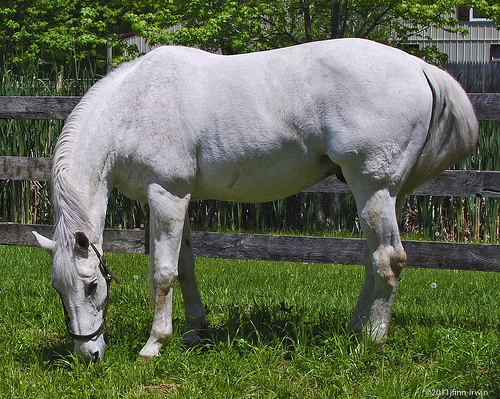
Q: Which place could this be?
A: It is a field.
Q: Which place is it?
A: It is a field.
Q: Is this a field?
A: Yes, it is a field.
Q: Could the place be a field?
A: Yes, it is a field.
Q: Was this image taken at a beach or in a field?
A: It was taken at a field.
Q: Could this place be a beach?
A: No, it is a field.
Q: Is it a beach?
A: No, it is a field.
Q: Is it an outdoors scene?
A: Yes, it is outdoors.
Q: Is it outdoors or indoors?
A: It is outdoors.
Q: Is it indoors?
A: No, it is outdoors.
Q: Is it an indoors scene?
A: No, it is outdoors.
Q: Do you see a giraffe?
A: No, there are no giraffes.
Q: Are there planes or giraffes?
A: No, there are no giraffes or planes.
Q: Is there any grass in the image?
A: Yes, there is grass.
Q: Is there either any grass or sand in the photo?
A: Yes, there is grass.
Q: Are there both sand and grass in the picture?
A: No, there is grass but no sand.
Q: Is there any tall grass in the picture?
A: Yes, there is tall grass.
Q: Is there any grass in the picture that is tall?
A: Yes, there is tall grass.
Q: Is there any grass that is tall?
A: Yes, there is grass that is tall.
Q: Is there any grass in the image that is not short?
A: Yes, there is tall grass.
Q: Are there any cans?
A: No, there are no cans.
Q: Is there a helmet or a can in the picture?
A: No, there are no cans or helmets.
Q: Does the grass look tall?
A: Yes, the grass is tall.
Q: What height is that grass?
A: The grass is tall.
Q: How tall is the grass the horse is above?
A: The grass is tall.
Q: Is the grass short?
A: No, the grass is tall.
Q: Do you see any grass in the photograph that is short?
A: No, there is grass but it is tall.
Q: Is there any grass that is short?
A: No, there is grass but it is tall.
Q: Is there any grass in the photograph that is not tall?
A: No, there is grass but it is tall.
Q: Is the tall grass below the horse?
A: Yes, the grass is below the horse.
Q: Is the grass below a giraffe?
A: No, the grass is below the horse.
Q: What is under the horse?
A: The grass is under the horse.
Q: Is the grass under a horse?
A: Yes, the grass is under a horse.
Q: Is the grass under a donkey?
A: No, the grass is under a horse.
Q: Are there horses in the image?
A: Yes, there is a horse.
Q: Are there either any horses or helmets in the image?
A: Yes, there is a horse.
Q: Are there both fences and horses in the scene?
A: Yes, there are both a horse and a fence.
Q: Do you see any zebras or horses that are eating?
A: Yes, the horse is eating.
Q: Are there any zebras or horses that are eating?
A: Yes, the horse is eating.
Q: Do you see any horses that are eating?
A: Yes, there is a horse that is eating.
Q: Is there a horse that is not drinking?
A: Yes, there is a horse that is eating.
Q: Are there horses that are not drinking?
A: Yes, there is a horse that is eating.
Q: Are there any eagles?
A: No, there are no eagles.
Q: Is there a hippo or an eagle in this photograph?
A: No, there are no eagles or hippos.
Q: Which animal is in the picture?
A: The animal is a horse.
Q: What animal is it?
A: The animal is a horse.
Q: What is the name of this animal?
A: This is a horse.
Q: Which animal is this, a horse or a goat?
A: This is a horse.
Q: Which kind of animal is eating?
A: The animal is a horse.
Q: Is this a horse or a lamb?
A: This is a horse.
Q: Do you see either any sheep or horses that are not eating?
A: No, there is a horse but it is eating.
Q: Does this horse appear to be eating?
A: Yes, the horse is eating.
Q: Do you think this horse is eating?
A: Yes, the horse is eating.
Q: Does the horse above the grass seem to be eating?
A: Yes, the horse is eating.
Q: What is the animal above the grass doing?
A: The horse is eating.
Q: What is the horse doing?
A: The horse is eating.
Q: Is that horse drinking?
A: No, the horse is eating.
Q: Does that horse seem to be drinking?
A: No, the horse is eating.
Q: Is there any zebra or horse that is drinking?
A: No, there is a horse but it is eating.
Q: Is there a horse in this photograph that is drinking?
A: No, there is a horse but it is eating.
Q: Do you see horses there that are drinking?
A: No, there is a horse but it is eating.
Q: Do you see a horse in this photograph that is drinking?
A: No, there is a horse but it is eating.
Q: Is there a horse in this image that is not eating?
A: No, there is a horse but it is eating.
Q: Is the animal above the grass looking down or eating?
A: The horse is eating.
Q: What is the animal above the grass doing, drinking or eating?
A: The horse is eating.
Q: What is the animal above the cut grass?
A: The animal is a horse.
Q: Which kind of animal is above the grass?
A: The animal is a horse.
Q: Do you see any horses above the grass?
A: Yes, there is a horse above the grass.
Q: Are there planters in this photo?
A: No, there are no planters.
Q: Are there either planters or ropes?
A: No, there are no planters or ropes.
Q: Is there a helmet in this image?
A: No, there are no helmets.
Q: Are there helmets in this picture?
A: No, there are no helmets.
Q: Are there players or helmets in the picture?
A: No, there are no helmets or players.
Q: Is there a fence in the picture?
A: Yes, there is a fence.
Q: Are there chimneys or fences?
A: Yes, there is a fence.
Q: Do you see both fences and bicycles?
A: No, there is a fence but no bikes.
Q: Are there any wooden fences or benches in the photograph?
A: Yes, there is a wood fence.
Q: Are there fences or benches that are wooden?
A: Yes, the fence is wooden.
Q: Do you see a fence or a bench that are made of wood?
A: Yes, the fence is made of wood.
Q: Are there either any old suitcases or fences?
A: Yes, there is an old fence.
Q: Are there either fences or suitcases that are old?
A: Yes, the fence is old.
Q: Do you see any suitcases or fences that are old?
A: Yes, the fence is old.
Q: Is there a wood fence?
A: Yes, there is a fence that is made of wood.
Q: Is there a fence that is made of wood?
A: Yes, there is a fence that is made of wood.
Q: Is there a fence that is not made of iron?
A: Yes, there is a fence that is made of wood.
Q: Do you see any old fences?
A: Yes, there is an old fence.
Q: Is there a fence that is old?
A: Yes, there is a fence that is old.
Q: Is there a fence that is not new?
A: Yes, there is a old fence.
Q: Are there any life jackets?
A: No, there are no life jackets.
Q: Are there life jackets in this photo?
A: No, there are no life jackets.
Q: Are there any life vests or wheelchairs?
A: No, there are no life vests or wheelchairs.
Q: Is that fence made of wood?
A: Yes, the fence is made of wood.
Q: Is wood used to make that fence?
A: Yes, the fence is made of wood.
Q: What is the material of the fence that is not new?
A: The fence is made of wood.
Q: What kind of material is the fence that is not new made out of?
A: The fence is made of wood.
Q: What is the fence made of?
A: The fence is made of wood.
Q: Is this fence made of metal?
A: No, the fence is made of wood.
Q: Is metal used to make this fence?
A: No, the fence is made of wood.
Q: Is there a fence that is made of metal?
A: No, there is a fence but it is made of wood.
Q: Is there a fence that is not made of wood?
A: No, there is a fence but it is made of wood.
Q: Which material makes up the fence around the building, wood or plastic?
A: The fence is made of wood.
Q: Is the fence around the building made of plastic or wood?
A: The fence is made of wood.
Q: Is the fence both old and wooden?
A: Yes, the fence is old and wooden.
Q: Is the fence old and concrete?
A: No, the fence is old but wooden.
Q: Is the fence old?
A: Yes, the fence is old.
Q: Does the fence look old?
A: Yes, the fence is old.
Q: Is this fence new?
A: No, the fence is old.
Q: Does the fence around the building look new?
A: No, the fence is old.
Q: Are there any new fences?
A: No, there is a fence but it is old.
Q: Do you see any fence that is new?
A: No, there is a fence but it is old.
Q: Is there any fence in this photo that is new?
A: No, there is a fence but it is old.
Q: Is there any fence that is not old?
A: No, there is a fence but it is old.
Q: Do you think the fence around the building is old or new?
A: The fence is old.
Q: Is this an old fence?
A: Yes, this is an old fence.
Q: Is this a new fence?
A: No, this is an old fence.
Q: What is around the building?
A: The fence is around the building.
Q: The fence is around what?
A: The fence is around the building.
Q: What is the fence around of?
A: The fence is around the building.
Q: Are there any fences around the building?
A: Yes, there is a fence around the building.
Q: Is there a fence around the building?
A: Yes, there is a fence around the building.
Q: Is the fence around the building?
A: Yes, the fence is around the building.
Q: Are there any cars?
A: No, there are no cars.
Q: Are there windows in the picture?
A: Yes, there is a window.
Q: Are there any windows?
A: Yes, there is a window.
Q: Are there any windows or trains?
A: Yes, there is a window.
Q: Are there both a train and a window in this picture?
A: No, there is a window but no trains.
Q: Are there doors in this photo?
A: No, there are no doors.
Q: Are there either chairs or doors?
A: No, there are no doors or chairs.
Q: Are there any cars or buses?
A: No, there are no cars or buses.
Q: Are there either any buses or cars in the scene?
A: No, there are no cars or buses.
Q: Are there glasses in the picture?
A: No, there are no glasses.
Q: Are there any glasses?
A: No, there are no glasses.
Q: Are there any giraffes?
A: No, there are no giraffes.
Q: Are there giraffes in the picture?
A: No, there are no giraffes.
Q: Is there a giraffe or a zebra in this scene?
A: No, there are no giraffes or zebras.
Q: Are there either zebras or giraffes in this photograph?
A: No, there are no giraffes or zebras.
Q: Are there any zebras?
A: No, there are no zebras.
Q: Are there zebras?
A: No, there are no zebras.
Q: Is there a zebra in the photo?
A: No, there are no zebras.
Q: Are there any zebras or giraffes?
A: No, there are no zebras or giraffes.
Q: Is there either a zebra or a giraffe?
A: No, there are no zebras or giraffes.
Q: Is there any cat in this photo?
A: No, there are no cats.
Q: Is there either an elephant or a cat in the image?
A: No, there are no cats or elephants.